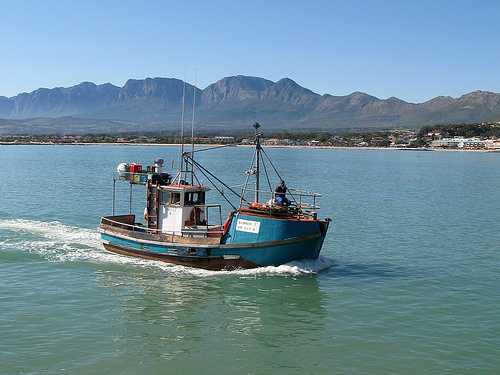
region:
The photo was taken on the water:
[28, 54, 465, 371]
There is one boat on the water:
[83, 108, 370, 308]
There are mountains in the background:
[52, 44, 494, 280]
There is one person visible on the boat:
[211, 144, 345, 279]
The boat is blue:
[96, 122, 376, 330]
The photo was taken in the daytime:
[26, 54, 470, 364]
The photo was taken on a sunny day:
[33, 16, 449, 331]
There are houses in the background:
[38, 114, 498, 191]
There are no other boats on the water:
[44, 99, 461, 347]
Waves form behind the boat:
[49, 51, 412, 356]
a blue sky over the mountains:
[0, 0, 499, 105]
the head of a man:
[276, 176, 286, 186]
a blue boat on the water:
[93, 182, 335, 274]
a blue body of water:
[1, 140, 499, 374]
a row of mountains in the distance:
[0, 71, 499, 129]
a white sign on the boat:
[234, 217, 259, 233]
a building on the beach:
[428, 135, 498, 152]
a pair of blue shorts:
[275, 194, 292, 204]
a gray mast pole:
[251, 130, 267, 211]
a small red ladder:
[143, 178, 160, 235]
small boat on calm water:
[64, 97, 406, 308]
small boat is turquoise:
[82, 202, 322, 279]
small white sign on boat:
[219, 214, 266, 251]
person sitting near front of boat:
[248, 172, 313, 227]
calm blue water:
[332, 140, 460, 333]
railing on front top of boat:
[212, 176, 329, 232]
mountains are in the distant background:
[9, 37, 420, 125]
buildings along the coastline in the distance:
[306, 129, 493, 166]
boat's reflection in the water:
[95, 274, 425, 360]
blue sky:
[85, 10, 405, 85]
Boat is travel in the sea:
[85, 102, 348, 294]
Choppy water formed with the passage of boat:
[8, 207, 98, 279]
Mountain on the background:
[0, 64, 497, 128]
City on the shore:
[199, 119, 496, 151]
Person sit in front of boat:
[270, 174, 297, 212]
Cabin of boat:
[139, 171, 218, 242]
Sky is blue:
[1, 1, 496, 73]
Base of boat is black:
[103, 247, 262, 287]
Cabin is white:
[141, 176, 213, 238]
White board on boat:
[229, 213, 265, 237]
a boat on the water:
[100, 76, 329, 272]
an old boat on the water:
[98, 55, 332, 274]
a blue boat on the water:
[94, 61, 336, 268]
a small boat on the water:
[99, 57, 331, 273]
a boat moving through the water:
[7, 68, 331, 280]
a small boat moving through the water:
[0, 83, 329, 272]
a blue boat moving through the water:
[5, 77, 337, 272]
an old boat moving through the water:
[0, 67, 336, 287]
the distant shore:
[0, 126, 497, 164]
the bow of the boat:
[275, 180, 341, 277]